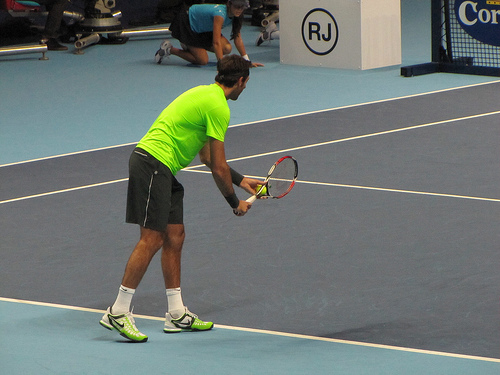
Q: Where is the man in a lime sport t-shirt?
A: Tennis court.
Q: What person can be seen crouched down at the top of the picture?
A: The ball girl.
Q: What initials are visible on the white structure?
A: RJ.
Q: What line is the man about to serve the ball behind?
A: The baseline.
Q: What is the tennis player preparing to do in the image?
A: Serve the ball.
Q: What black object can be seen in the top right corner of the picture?
A: The net.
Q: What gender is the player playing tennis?
A: Male.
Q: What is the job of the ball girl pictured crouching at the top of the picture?
A: Retrieve the tennis balls.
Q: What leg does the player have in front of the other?
A: His left.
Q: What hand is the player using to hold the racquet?
A: His right hand.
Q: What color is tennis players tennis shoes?
A: Green, white and black.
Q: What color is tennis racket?
A: White, red and black.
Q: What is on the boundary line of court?
A: The leg of a man.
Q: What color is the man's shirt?
A: Green.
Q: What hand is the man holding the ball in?
A: His left hand.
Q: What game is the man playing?
A: Tennis.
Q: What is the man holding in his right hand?
A: A tennis racket.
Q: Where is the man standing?
A: On a tennis court.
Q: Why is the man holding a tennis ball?
A: He is about to serve.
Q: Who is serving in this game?
A: The man shown.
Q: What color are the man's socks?
A: White.